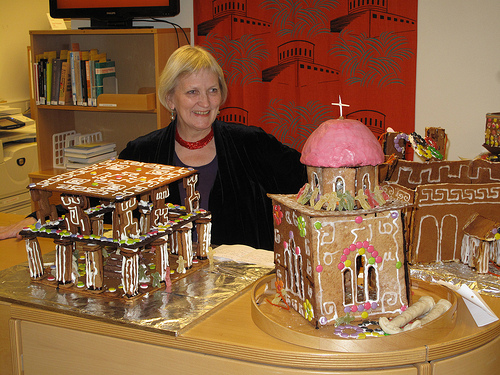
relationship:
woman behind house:
[113, 45, 306, 255] [15, 157, 210, 304]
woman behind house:
[113, 45, 306, 255] [264, 120, 411, 330]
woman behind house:
[113, 45, 306, 255] [380, 157, 497, 274]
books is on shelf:
[30, 39, 118, 109] [32, 95, 161, 113]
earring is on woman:
[162, 98, 185, 125] [118, 28, 328, 283]